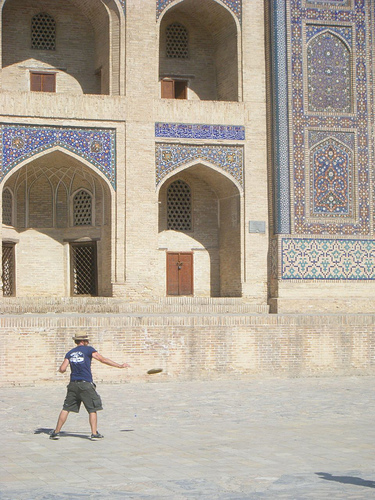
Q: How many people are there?
A: One.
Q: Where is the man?
A: In an outdoor courtyard.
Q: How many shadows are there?
A: Three.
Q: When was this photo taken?
A: During the day.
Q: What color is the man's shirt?
A: Blue.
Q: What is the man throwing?
A: A frisbee.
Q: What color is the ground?
A: Grey.